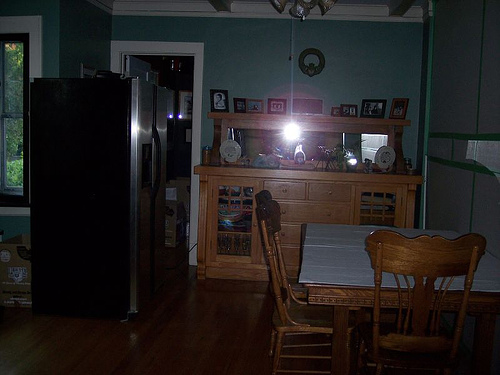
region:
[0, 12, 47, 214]
window to the left.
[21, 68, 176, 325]
A stainless steel refrigerator.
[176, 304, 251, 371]
The floors are made of wood.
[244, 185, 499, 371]
A table and chairs.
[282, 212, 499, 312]
The table has a cloth on the top of it.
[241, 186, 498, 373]
The table and chairs are made of wood.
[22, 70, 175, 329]
The sides of the refrigerator are black.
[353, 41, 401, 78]
The walls are green.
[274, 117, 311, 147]
A light glare.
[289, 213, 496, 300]
The table clothe is white.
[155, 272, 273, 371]
the floor is shiny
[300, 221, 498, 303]
the table has a white mat onit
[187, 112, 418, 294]
a large oak hutch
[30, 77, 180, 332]
the refrigerator is black and stainless steel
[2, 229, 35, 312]
a cardboard box behind the refrigerator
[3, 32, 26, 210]
a window without coverings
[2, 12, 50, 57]
the trim around the window is white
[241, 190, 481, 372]
there are two oak chairs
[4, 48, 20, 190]
trees are seen outside the window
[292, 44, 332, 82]
a small decoration on the wall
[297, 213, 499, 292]
a white mat on a table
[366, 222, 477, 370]
a wooden chair at a table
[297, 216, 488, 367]
a wooden dining table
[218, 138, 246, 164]
a decorative plate on display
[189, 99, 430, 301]
a brown wood china cabinet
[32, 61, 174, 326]
a black and silver colored refrigerator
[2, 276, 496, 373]
a brown hardwood floor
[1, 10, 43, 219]
a window in a wall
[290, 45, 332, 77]
a wreath hanging on a wall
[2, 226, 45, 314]
a brown box in a room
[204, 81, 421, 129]
picture display on a shelf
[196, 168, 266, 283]
paneled glass cupboard door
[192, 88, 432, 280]
wood hutch with glass doors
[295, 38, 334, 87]
wreath hanging on a wall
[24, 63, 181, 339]
black refrigerator with silver doors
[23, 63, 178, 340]
black refrigerator with two doors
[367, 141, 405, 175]
decorative plate on display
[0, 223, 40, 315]
empty cardboard box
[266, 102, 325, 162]
camera flash relection in mirror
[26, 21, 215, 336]
doorway with white trim partially blocked by refrigerator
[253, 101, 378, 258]
the tablecloth is white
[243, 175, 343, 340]
the chair is made of wood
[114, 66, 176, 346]
refrigerator doors are closed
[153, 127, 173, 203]
the handle is black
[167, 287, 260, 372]
the floor is brown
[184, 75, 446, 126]
picture frames on top of the drawer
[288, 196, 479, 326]
tablecloth on top of the table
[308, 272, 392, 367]
the table is brown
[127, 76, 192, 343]
refrigerator doors are silver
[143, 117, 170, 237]
the handle is black